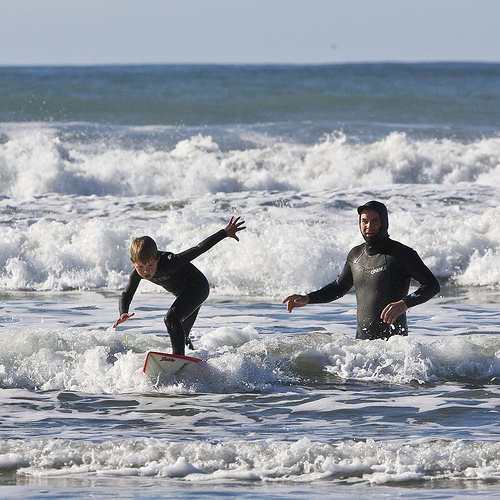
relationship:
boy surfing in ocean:
[110, 213, 247, 356] [0, 61, 499, 498]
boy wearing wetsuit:
[110, 213, 247, 356] [163, 256, 199, 354]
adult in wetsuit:
[280, 199, 442, 345] [350, 242, 413, 332]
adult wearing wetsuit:
[280, 199, 442, 345] [352, 229, 409, 337]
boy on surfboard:
[110, 213, 247, 356] [140, 352, 205, 382]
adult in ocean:
[283, 201, 441, 344] [0, 61, 499, 498]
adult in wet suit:
[280, 199, 442, 345] [303, 198, 440, 340]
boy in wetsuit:
[110, 213, 247, 356] [125, 226, 228, 344]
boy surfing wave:
[110, 213, 247, 356] [8, 316, 485, 405]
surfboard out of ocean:
[140, 347, 202, 381] [0, 61, 499, 498]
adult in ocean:
[280, 199, 442, 345] [2, 65, 499, 495]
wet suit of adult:
[303, 198, 440, 340] [280, 199, 442, 345]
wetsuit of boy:
[123, 219, 224, 343] [126, 223, 236, 343]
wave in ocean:
[8, 204, 498, 297] [2, 65, 499, 495]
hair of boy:
[128, 236, 158, 264] [110, 213, 247, 356]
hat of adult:
[354, 199, 396, 215] [280, 199, 442, 345]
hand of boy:
[223, 210, 246, 241] [110, 213, 247, 356]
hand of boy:
[117, 311, 136, 329] [110, 213, 247, 356]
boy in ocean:
[110, 213, 247, 356] [0, 61, 499, 498]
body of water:
[0, 60, 499, 500] [243, 259, 343, 357]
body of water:
[0, 60, 499, 500] [226, 317, 278, 409]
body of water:
[0, 60, 499, 500] [232, 134, 324, 402]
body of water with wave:
[45, 110, 490, 500] [54, 158, 423, 331]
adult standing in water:
[280, 199, 442, 345] [54, 215, 496, 489]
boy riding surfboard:
[110, 213, 247, 356] [119, 345, 224, 395]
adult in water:
[280, 199, 442, 345] [32, 224, 492, 500]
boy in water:
[110, 213, 247, 356] [32, 224, 492, 500]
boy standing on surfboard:
[110, 213, 247, 356] [137, 343, 215, 383]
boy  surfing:
[110, 213, 247, 356] [114, 334, 232, 414]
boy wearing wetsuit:
[101, 184, 236, 400] [160, 265, 190, 305]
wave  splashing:
[43, 194, 430, 396] [20, 442, 489, 500]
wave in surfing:
[9, 165, 489, 500] [112, 215, 247, 390]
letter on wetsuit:
[367, 265, 388, 278] [292, 200, 439, 397]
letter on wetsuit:
[367, 265, 388, 278] [287, 189, 437, 380]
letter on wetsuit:
[367, 265, 388, 278] [280, 175, 441, 429]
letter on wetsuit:
[374, 269, 382, 273] [281, 187, 447, 451]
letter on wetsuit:
[152, 273, 172, 284] [105, 224, 245, 383]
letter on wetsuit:
[152, 273, 172, 284] [117, 229, 237, 402]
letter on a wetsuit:
[160, 276, 169, 286] [154, 264, 198, 354]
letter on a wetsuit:
[152, 273, 172, 284] [168, 259, 192, 340]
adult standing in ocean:
[280, 199, 442, 345] [0, 61, 499, 498]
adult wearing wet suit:
[280, 199, 442, 345] [275, 196, 445, 340]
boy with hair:
[110, 213, 247, 356] [125, 236, 157, 265]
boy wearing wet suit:
[110, 213, 247, 356] [112, 222, 220, 348]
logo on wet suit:
[368, 265, 385, 277] [295, 191, 443, 333]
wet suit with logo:
[295, 191, 443, 333] [368, 265, 385, 277]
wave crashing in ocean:
[0, 121, 499, 297] [2, 65, 499, 495]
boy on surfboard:
[110, 213, 247, 356] [135, 343, 207, 380]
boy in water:
[110, 213, 247, 356] [23, 136, 464, 496]